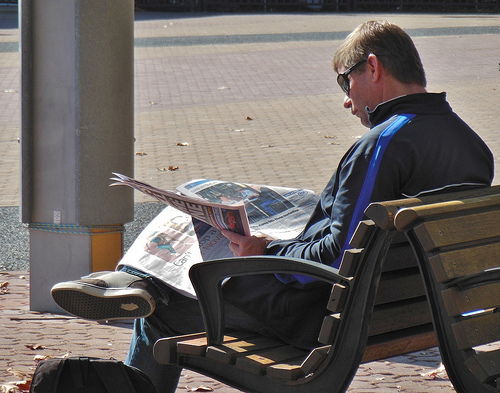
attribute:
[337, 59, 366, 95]
sunglasses — black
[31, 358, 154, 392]
bag — black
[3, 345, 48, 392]
leaves — dead, brown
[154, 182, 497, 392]
bench — wooden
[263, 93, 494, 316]
windbreaker — black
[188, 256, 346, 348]
armrest — metal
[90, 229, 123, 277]
panel — yellow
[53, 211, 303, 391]
legs — crossed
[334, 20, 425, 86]
hair — short